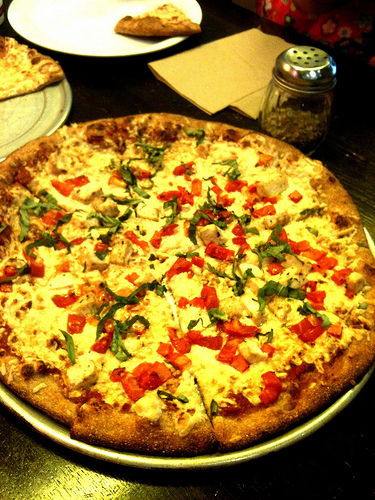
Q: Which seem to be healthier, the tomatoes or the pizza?
A: The tomatoes are healthier than the pizza.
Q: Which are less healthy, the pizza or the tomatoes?
A: The pizza are less healthy than the tomatoes.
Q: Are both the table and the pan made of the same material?
A: No, the table is made of wood and the pan is made of metal.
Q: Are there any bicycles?
A: No, there are no bicycles.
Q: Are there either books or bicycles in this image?
A: No, there are no bicycles or books.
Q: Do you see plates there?
A: Yes, there is a plate.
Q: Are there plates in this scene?
A: Yes, there is a plate.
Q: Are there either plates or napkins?
A: Yes, there is a plate.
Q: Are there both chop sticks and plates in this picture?
A: No, there is a plate but no chopsticks.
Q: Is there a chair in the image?
A: No, there are no chairs.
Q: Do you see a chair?
A: No, there are no chairs.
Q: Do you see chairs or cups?
A: No, there are no chairs or cups.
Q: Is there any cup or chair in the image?
A: No, there are no chairs or cups.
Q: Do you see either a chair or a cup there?
A: No, there are no chairs or cups.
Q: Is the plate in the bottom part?
A: No, the plate is in the top of the image.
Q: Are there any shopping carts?
A: No, there are no shopping carts.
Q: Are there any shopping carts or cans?
A: No, there are no shopping carts or cans.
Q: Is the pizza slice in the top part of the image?
A: Yes, the pizza slice is in the top of the image.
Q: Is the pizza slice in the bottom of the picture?
A: No, the pizza slice is in the top of the image.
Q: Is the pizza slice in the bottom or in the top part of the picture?
A: The pizza slice is in the top of the image.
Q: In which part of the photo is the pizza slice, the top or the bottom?
A: The pizza slice is in the top of the image.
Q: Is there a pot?
A: No, there are no pots.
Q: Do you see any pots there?
A: No, there are no pots.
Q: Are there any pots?
A: No, there are no pots.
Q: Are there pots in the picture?
A: No, there are no pots.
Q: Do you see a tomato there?
A: Yes, there are tomatoes.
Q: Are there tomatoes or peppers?
A: Yes, there are tomatoes.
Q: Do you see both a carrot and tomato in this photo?
A: No, there are tomatoes but no carrots.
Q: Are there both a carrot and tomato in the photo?
A: No, there are tomatoes but no carrots.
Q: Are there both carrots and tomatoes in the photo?
A: No, there are tomatoes but no carrots.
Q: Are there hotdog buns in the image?
A: No, there are no hotdog buns.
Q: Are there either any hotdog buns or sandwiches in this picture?
A: No, there are no hotdog buns or sandwiches.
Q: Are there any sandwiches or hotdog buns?
A: No, there are no hotdog buns or sandwiches.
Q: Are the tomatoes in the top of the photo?
A: No, the tomatoes are in the bottom of the image.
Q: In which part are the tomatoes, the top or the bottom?
A: The tomatoes are in the bottom of the image.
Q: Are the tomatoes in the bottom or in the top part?
A: The tomatoes are in the bottom of the image.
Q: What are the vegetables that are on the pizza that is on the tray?
A: The vegetables are tomatoes.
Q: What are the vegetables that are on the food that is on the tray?
A: The vegetables are tomatoes.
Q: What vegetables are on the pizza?
A: The vegetables are tomatoes.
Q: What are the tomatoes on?
A: The tomatoes are on the pizza.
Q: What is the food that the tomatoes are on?
A: The food is a pizza.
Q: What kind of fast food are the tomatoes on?
A: The tomatoes are on the pizza.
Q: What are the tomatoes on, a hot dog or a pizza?
A: The tomatoes are on a pizza.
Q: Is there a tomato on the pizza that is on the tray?
A: Yes, there are tomatoes on the pizza.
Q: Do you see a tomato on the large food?
A: Yes, there are tomatoes on the pizza.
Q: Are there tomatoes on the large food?
A: Yes, there are tomatoes on the pizza.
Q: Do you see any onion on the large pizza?
A: No, there are tomatoes on the pizza.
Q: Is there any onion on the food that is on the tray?
A: No, there are tomatoes on the pizza.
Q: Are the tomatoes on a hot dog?
A: No, the tomatoes are on the pizza.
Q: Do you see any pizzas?
A: Yes, there is a pizza.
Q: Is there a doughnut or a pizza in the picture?
A: Yes, there is a pizza.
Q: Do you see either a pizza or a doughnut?
A: Yes, there is a pizza.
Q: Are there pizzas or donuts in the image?
A: Yes, there is a pizza.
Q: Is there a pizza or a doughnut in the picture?
A: Yes, there is a pizza.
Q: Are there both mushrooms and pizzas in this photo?
A: No, there is a pizza but no mushrooms.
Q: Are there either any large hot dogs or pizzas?
A: Yes, there is a large pizza.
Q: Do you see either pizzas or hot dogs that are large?
A: Yes, the pizza is large.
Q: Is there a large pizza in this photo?
A: Yes, there is a large pizza.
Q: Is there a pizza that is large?
A: Yes, there is a pizza that is large.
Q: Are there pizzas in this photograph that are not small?
A: Yes, there is a large pizza.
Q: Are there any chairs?
A: No, there are no chairs.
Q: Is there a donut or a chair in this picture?
A: No, there are no chairs or donuts.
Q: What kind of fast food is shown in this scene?
A: The fast food is a pizza.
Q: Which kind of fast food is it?
A: The food is a pizza.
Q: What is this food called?
A: This is a pizza.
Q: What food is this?
A: This is a pizza.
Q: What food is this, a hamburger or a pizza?
A: This is a pizza.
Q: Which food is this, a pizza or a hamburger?
A: This is a pizza.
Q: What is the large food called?
A: The food is a pizza.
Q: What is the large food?
A: The food is a pizza.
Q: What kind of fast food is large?
A: The fast food is a pizza.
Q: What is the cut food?
A: The food is a pizza.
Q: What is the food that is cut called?
A: The food is a pizza.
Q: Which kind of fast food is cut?
A: The fast food is a pizza.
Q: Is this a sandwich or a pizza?
A: This is a pizza.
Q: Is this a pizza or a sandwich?
A: This is a pizza.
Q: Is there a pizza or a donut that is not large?
A: No, there is a pizza but it is large.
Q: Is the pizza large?
A: Yes, the pizza is large.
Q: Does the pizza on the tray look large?
A: Yes, the pizza is large.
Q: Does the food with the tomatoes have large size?
A: Yes, the pizza is large.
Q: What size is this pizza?
A: The pizza is large.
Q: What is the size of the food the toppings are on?
A: The pizza is large.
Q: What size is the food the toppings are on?
A: The pizza is large.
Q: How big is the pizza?
A: The pizza is large.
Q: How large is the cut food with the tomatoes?
A: The pizza is large.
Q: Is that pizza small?
A: No, the pizza is large.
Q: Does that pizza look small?
A: No, the pizza is large.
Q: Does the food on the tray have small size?
A: No, the pizza is large.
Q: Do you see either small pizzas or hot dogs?
A: No, there is a pizza but it is large.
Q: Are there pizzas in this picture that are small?
A: No, there is a pizza but it is large.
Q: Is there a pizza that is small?
A: No, there is a pizza but it is large.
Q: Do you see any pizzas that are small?
A: No, there is a pizza but it is large.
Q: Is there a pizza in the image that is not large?
A: No, there is a pizza but it is large.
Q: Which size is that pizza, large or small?
A: The pizza is large.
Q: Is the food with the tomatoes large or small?
A: The pizza is large.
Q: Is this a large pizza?
A: Yes, this is a large pizza.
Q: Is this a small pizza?
A: No, this is a large pizza.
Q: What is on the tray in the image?
A: The pizza is on the tray.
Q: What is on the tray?
A: The pizza is on the tray.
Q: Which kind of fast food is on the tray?
A: The food is a pizza.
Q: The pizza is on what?
A: The pizza is on the tray.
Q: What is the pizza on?
A: The pizza is on the tray.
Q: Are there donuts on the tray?
A: No, there is a pizza on the tray.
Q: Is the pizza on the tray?
A: Yes, the pizza is on the tray.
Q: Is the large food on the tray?
A: Yes, the pizza is on the tray.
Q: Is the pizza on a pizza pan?
A: No, the pizza is on the tray.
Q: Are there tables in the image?
A: Yes, there is a table.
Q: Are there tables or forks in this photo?
A: Yes, there is a table.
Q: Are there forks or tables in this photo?
A: Yes, there is a table.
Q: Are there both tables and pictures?
A: No, there is a table but no pictures.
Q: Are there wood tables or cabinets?
A: Yes, there is a wood table.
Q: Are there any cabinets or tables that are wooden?
A: Yes, the table is wooden.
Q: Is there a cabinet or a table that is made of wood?
A: Yes, the table is made of wood.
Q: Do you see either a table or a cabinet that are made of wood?
A: Yes, the table is made of wood.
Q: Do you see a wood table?
A: Yes, there is a table that is made of wood.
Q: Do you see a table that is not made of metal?
A: Yes, there is a table that is made of wood.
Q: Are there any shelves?
A: No, there are no shelves.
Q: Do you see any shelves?
A: No, there are no shelves.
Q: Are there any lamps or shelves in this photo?
A: No, there are no shelves or lamps.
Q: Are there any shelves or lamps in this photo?
A: No, there are no shelves or lamps.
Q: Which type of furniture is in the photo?
A: The furniture is a table.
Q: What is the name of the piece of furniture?
A: The piece of furniture is a table.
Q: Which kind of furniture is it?
A: The piece of furniture is a table.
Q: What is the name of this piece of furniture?
A: This is a table.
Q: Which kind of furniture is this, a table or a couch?
A: This is a table.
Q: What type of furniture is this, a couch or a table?
A: This is a table.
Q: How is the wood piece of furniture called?
A: The piece of furniture is a table.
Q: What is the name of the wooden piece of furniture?
A: The piece of furniture is a table.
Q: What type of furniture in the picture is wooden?
A: The furniture is a table.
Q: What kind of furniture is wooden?
A: The furniture is a table.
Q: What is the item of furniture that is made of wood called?
A: The piece of furniture is a table.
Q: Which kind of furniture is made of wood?
A: The furniture is a table.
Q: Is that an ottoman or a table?
A: That is a table.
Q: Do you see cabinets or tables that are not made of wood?
A: No, there is a table but it is made of wood.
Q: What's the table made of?
A: The table is made of wood.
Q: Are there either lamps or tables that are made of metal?
A: No, there is a table but it is made of wood.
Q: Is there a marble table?
A: No, there is a table but it is made of wood.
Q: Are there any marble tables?
A: No, there is a table but it is made of wood.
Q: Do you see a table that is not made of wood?
A: No, there is a table but it is made of wood.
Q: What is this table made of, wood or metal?
A: The table is made of wood.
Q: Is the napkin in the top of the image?
A: Yes, the napkin is in the top of the image.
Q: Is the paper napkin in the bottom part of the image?
A: No, the napkin is in the top of the image.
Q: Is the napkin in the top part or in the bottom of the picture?
A: The napkin is in the top of the image.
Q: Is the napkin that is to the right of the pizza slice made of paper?
A: Yes, the napkin is made of paper.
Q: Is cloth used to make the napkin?
A: No, the napkin is made of paper.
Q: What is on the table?
A: The napkin is on the table.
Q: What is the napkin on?
A: The napkin is on the table.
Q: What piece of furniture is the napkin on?
A: The napkin is on the table.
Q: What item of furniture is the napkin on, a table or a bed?
A: The napkin is on a table.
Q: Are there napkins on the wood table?
A: Yes, there is a napkin on the table.